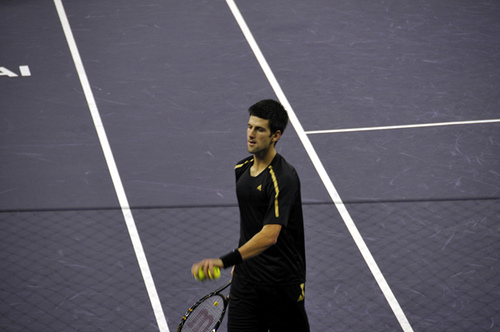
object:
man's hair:
[246, 100, 289, 135]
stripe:
[259, 168, 286, 224]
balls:
[196, 224, 237, 292]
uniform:
[162, 149, 378, 307]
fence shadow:
[11, 192, 352, 257]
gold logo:
[253, 181, 273, 201]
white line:
[349, 250, 400, 270]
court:
[331, 243, 455, 291]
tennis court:
[289, 70, 499, 330]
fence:
[2, 191, 497, 330]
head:
[232, 93, 297, 166]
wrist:
[212, 234, 252, 278]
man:
[206, 93, 306, 328]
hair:
[246, 93, 290, 143]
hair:
[247, 94, 288, 147]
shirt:
[229, 153, 311, 279]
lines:
[54, 1, 497, 330]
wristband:
[219, 249, 243, 268]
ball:
[205, 265, 222, 284]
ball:
[189, 265, 208, 285]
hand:
[189, 255, 222, 282]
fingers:
[190, 257, 217, 279]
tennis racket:
[175, 280, 237, 328]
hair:
[247, 96, 287, 134]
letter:
[190, 307, 213, 330]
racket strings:
[176, 290, 229, 330]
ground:
[1, 1, 497, 328]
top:
[220, 153, 306, 287]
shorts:
[178, 271, 333, 323]